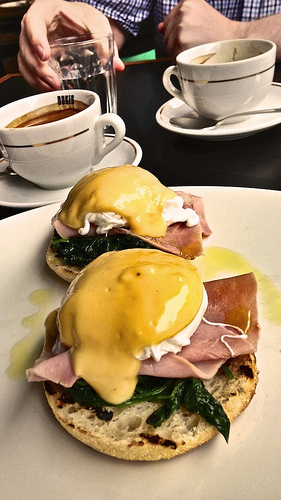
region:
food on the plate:
[2, 202, 247, 458]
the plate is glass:
[56, 475, 94, 496]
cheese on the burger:
[113, 183, 147, 210]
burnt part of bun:
[122, 429, 174, 455]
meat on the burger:
[212, 304, 236, 360]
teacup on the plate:
[165, 31, 276, 128]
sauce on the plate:
[206, 249, 263, 279]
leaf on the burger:
[157, 385, 229, 435]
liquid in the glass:
[48, 49, 111, 81]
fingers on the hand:
[14, 12, 62, 77]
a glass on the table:
[61, 39, 115, 90]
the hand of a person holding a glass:
[19, 0, 122, 93]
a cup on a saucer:
[181, 43, 264, 102]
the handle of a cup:
[165, 64, 183, 96]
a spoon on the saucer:
[170, 116, 250, 130]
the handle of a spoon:
[227, 109, 280, 118]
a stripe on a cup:
[13, 144, 57, 149]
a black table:
[174, 141, 266, 181]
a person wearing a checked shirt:
[113, 1, 144, 24]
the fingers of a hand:
[17, 18, 56, 91]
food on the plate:
[37, 173, 262, 405]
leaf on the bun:
[171, 394, 220, 427]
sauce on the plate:
[227, 250, 249, 276]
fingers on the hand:
[15, 28, 53, 64]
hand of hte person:
[163, 3, 227, 39]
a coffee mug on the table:
[166, 42, 277, 130]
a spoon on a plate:
[170, 111, 278, 127]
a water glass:
[46, 32, 113, 91]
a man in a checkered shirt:
[20, 0, 279, 40]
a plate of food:
[9, 187, 254, 401]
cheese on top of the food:
[68, 251, 155, 385]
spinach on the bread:
[125, 375, 257, 421]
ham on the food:
[150, 290, 255, 350]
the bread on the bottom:
[74, 390, 205, 428]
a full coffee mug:
[12, 89, 121, 155]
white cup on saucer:
[25, 73, 96, 180]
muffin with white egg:
[39, 264, 231, 458]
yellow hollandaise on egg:
[69, 284, 220, 458]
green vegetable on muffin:
[73, 369, 264, 435]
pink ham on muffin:
[51, 261, 266, 430]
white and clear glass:
[51, 38, 133, 133]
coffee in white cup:
[6, 104, 114, 180]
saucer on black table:
[18, 125, 133, 211]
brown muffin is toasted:
[45, 285, 239, 462]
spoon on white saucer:
[169, 88, 279, 128]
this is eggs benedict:
[46, 346, 192, 443]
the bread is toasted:
[78, 394, 179, 460]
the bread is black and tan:
[65, 398, 157, 466]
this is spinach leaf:
[147, 377, 226, 422]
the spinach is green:
[143, 359, 235, 455]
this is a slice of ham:
[165, 345, 230, 379]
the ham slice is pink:
[151, 353, 228, 382]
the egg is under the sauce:
[91, 269, 189, 353]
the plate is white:
[201, 433, 276, 497]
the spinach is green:
[143, 380, 224, 429]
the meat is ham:
[202, 280, 255, 373]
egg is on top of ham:
[173, 305, 254, 370]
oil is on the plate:
[201, 239, 280, 286]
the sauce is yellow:
[73, 258, 172, 395]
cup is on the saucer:
[11, 128, 127, 194]